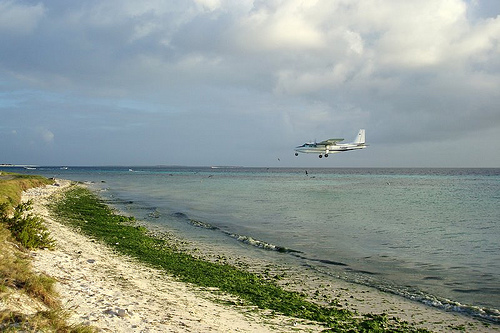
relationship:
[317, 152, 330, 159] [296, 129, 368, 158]
wheels on plane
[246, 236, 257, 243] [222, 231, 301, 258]
cap on wave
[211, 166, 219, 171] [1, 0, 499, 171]
boat in background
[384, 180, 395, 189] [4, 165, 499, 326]
buoy in sea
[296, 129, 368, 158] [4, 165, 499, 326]
plane over water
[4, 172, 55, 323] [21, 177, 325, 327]
grass on sand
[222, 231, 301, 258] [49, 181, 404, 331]
wave in ocean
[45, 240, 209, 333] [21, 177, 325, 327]
tracks in sand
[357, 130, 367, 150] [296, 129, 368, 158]
tail of plane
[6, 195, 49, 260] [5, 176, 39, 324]
plants on hill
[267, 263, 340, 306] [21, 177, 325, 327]
rocks on sand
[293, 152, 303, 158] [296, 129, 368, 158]
wheel on plane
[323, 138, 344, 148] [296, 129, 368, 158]
wing of plane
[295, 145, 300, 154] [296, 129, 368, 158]
nose of plane